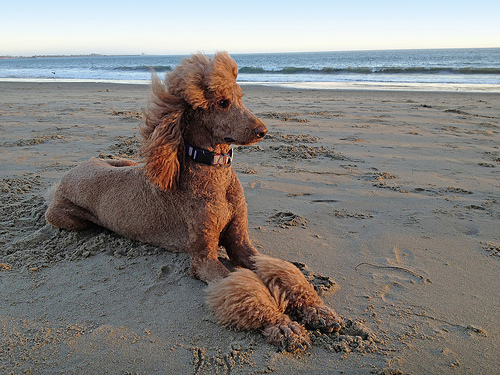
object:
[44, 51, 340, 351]
poodle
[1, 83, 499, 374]
beach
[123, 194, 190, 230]
brown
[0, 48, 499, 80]
ocean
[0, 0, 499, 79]
background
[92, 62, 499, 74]
waves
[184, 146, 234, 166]
collar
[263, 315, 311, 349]
dog's paws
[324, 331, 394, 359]
sand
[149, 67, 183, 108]
dog's hair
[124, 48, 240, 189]
poodle haircut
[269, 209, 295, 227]
foot prints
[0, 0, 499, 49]
clear sky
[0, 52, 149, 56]
land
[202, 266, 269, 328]
tufts of hair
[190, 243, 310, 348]
poodle's legs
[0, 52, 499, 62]
line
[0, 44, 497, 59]
horizon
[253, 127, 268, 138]
nose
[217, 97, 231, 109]
eye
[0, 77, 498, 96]
wet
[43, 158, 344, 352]
sitting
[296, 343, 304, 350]
claws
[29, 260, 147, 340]
brown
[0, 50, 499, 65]
calm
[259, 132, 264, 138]
black